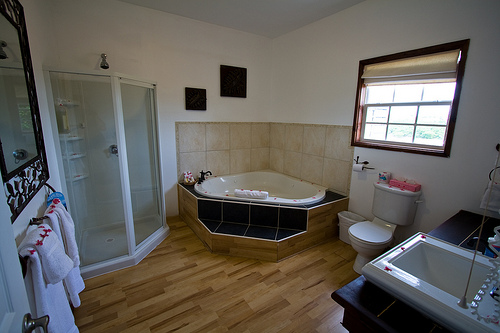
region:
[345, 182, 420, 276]
A white toilet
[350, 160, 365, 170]
A toiler paper roll on the holder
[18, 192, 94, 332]
Towels on a towel rack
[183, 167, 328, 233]
A bath in the corner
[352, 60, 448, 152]
A closed window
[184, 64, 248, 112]
Pictures hanging on the wall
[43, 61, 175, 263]
A shower in the corner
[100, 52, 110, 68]
A silver shower head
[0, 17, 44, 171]
A mirror on the wall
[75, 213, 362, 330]
A wooden floor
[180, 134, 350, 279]
a tub in the corner of a room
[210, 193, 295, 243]
black tile on stairs of a tub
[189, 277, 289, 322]
a light colored wood floor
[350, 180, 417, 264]
a white porcelain toilet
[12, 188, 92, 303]
towels hanging on a rack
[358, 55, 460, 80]
blinds on a window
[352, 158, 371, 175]
toilet paper on a dispenser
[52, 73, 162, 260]
a glass shower enclosure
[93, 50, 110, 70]
a shower head on the wall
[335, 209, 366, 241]
a white waste bucket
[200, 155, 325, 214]
large bathtub in room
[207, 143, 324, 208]
triangle bathtub in bathroom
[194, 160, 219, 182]
faucet for bathtub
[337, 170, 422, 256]
white toilet in room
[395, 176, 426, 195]
pink objects on top of toilet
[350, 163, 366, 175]
white toilet paper on a roll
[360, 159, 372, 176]
metal toilet paper holder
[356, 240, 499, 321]
white sink in bathroom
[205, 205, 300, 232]
blue tile on floor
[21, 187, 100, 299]
white towels hanging from rack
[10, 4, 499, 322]
a master bathroom in a house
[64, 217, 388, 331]
the floor is light wood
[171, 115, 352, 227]
wall tile is behind the jacuzzi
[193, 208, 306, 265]
a tiled step leads up to the tub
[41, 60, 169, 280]
a glass enclosed shower is next to the tub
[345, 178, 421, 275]
a toilet is under the window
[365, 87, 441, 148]
the bathroom window has mullions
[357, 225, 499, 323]
a square sink is in the bathroom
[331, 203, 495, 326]
the counter top is tiled around the sink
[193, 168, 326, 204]
large white corner bath tub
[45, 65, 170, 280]
tempered glass shower doors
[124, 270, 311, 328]
wood plank bathroom floor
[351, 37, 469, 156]
twelve pane bathroom window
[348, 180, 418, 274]
white porcelain toilet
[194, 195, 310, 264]
wood and tiled step to bath tub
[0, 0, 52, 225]
black ornate metal framed mirror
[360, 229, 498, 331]
white porcelain above counter top sink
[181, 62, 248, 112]
two black squares on white wall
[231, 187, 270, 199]
large white rolled bath towel